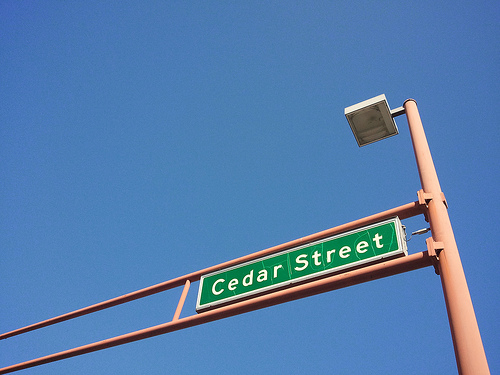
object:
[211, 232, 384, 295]
cedar street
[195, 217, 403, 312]
sign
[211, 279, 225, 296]
c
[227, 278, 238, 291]
e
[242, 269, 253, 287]
d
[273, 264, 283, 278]
r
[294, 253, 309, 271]
s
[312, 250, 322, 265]
t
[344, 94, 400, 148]
light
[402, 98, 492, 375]
post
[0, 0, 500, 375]
sky